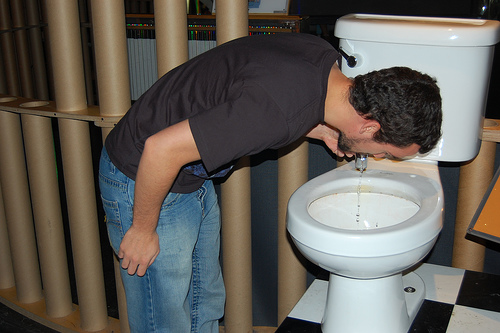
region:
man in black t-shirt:
[97, 32, 442, 332]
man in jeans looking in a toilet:
[97, 31, 442, 331]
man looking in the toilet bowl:
[284, 164, 444, 331]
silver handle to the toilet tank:
[338, 45, 358, 67]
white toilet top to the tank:
[333, 13, 498, 47]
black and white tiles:
[272, 262, 498, 331]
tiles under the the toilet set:
[270, 260, 498, 331]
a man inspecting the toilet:
[97, 31, 444, 331]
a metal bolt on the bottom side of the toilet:
[404, 285, 415, 293]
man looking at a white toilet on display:
[285, 12, 497, 331]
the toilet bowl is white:
[195, 70, 457, 322]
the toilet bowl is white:
[301, 108, 492, 330]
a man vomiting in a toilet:
[154, 10, 479, 298]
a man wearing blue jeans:
[72, 99, 267, 327]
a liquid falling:
[345, 153, 386, 218]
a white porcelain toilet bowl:
[285, 178, 436, 309]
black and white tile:
[429, 282, 495, 332]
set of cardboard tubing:
[11, 90, 97, 310]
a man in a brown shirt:
[103, 21, 370, 235]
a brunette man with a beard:
[345, 37, 412, 159]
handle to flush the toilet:
[336, 40, 368, 75]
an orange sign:
[465, 183, 499, 263]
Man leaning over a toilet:
[111, 35, 467, 327]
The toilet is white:
[312, 1, 487, 328]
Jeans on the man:
[72, 117, 244, 330]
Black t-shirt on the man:
[90, 27, 375, 204]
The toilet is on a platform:
[272, 0, 497, 331]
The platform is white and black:
[277, 237, 497, 331]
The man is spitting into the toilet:
[329, 143, 397, 243]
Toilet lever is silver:
[330, 32, 374, 70]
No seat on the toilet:
[251, 137, 457, 279]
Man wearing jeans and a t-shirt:
[70, 23, 442, 330]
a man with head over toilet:
[83, 27, 499, 287]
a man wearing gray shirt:
[69, 39, 464, 306]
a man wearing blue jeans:
[60, 17, 464, 330]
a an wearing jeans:
[43, 35, 448, 280]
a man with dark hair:
[224, 28, 447, 214]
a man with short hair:
[237, 27, 487, 179]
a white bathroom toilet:
[289, 4, 499, 316]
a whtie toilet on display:
[291, 15, 482, 331]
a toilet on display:
[285, 3, 488, 320]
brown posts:
[12, 42, 357, 319]